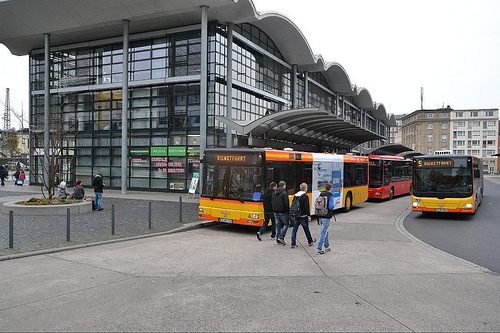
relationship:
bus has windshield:
[205, 129, 374, 211] [202, 157, 267, 202]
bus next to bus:
[205, 129, 374, 211] [411, 140, 478, 223]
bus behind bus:
[370, 145, 410, 195] [205, 129, 374, 211]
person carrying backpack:
[313, 190, 340, 236] [313, 196, 330, 218]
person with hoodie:
[313, 190, 340, 236] [326, 194, 335, 214]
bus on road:
[205, 129, 374, 211] [174, 228, 247, 300]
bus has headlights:
[205, 129, 374, 211] [191, 202, 261, 230]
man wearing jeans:
[295, 179, 311, 237] [289, 215, 314, 244]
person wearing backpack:
[313, 190, 340, 236] [313, 196, 330, 218]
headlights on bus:
[191, 202, 261, 230] [205, 129, 374, 211]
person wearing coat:
[268, 170, 293, 242] [272, 194, 289, 215]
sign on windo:
[134, 157, 165, 170] [140, 124, 175, 167]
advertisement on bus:
[143, 147, 190, 190] [205, 129, 374, 211]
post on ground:
[101, 200, 125, 239] [85, 217, 112, 244]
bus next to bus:
[205, 129, 374, 211] [403, 153, 485, 226]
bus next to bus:
[205, 129, 374, 211] [401, 152, 481, 223]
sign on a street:
[181, 170, 201, 194] [2, 180, 496, 331]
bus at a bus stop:
[205, 129, 374, 211] [2, 153, 430, 331]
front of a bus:
[199, 147, 264, 227] [205, 129, 374, 211]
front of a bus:
[412, 157, 473, 215] [205, 129, 374, 211]